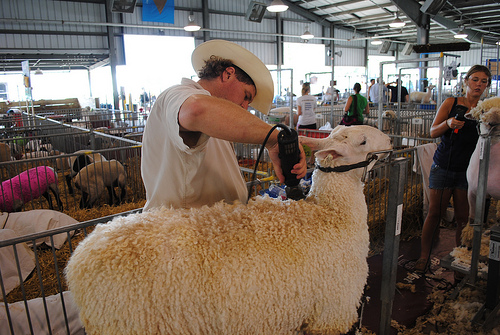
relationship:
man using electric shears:
[138, 38, 308, 213] [246, 124, 303, 200]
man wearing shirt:
[138, 38, 308, 213] [139, 78, 248, 214]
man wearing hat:
[138, 38, 308, 213] [191, 38, 274, 115]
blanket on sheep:
[2, 165, 57, 211] [1, 165, 64, 213]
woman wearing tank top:
[414, 63, 492, 273] [432, 97, 484, 170]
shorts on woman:
[430, 160, 469, 189] [414, 63, 492, 273]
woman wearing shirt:
[343, 82, 370, 125] [348, 94, 368, 122]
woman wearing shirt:
[297, 82, 317, 130] [298, 94, 317, 126]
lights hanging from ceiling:
[183, 1, 499, 48] [289, 1, 500, 47]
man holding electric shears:
[138, 38, 308, 213] [246, 124, 303, 200]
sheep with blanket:
[1, 165, 64, 213] [2, 165, 57, 211]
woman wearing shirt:
[386, 78, 410, 103] [389, 82, 408, 102]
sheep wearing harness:
[64, 123, 394, 334] [313, 154, 378, 171]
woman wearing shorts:
[414, 63, 492, 273] [430, 160, 469, 189]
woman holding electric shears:
[414, 63, 492, 273] [421, 104, 471, 291]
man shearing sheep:
[138, 38, 308, 213] [64, 123, 394, 334]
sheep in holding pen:
[1, 165, 64, 213] [1, 129, 148, 215]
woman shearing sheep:
[414, 63, 492, 273] [460, 97, 499, 251]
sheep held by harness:
[64, 123, 394, 334] [313, 154, 378, 171]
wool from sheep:
[454, 231, 490, 269] [460, 97, 499, 251]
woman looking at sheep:
[343, 82, 370, 125] [361, 107, 397, 133]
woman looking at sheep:
[297, 82, 317, 130] [410, 83, 435, 105]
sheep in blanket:
[1, 165, 64, 213] [2, 165, 57, 211]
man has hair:
[138, 38, 308, 213] [198, 54, 256, 84]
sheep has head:
[64, 123, 394, 334] [316, 124, 390, 175]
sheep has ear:
[64, 123, 394, 334] [315, 146, 346, 162]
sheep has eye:
[64, 123, 394, 334] [359, 139, 367, 146]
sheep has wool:
[64, 123, 394, 334] [63, 165, 370, 335]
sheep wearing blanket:
[1, 165, 64, 213] [2, 165, 57, 211]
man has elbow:
[138, 38, 308, 213] [187, 97, 210, 119]